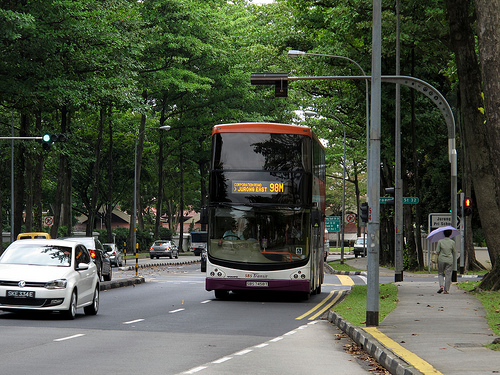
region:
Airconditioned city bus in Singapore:
[203, 123, 323, 298]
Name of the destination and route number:
[232, 180, 286, 198]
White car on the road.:
[0, 231, 97, 318]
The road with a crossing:
[0, 253, 360, 373]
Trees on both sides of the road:
[0, 80, 495, 270]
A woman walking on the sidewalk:
[435, 225, 455, 290]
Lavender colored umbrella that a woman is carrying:
[425, 225, 455, 236]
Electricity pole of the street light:
[365, 0, 377, 320]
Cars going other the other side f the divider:
[19, 233, 209, 277]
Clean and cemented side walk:
[347, 258, 498, 373]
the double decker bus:
[198, 104, 330, 309]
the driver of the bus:
[214, 215, 250, 250]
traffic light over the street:
[230, 61, 410, 131]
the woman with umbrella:
[411, 218, 461, 302]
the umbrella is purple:
[422, 216, 477, 242]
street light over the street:
[266, 31, 348, 80]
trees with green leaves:
[10, 10, 492, 115]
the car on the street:
[4, 233, 112, 311]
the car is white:
[5, 231, 107, 323]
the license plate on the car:
[3, 286, 37, 308]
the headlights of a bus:
[288, 270, 312, 282]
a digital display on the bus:
[226, 175, 291, 200]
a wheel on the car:
[61, 286, 81, 320]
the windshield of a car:
[0, 240, 76, 272]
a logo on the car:
[15, 275, 30, 291]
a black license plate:
[3, 285, 37, 303]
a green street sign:
[373, 193, 421, 207]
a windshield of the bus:
[204, 194, 312, 269]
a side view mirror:
[74, 259, 95, 273]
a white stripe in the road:
[158, 300, 189, 320]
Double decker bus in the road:
[182, 122, 314, 309]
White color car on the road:
[11, 248, 88, 331]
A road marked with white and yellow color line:
[162, 298, 318, 347]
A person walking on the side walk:
[423, 219, 468, 299]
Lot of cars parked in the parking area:
[93, 227, 178, 260]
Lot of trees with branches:
[58, 40, 200, 82]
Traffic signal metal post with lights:
[250, 69, 342, 100]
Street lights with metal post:
[280, 47, 360, 66]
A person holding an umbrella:
[423, 222, 458, 250]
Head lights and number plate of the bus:
[208, 266, 308, 290]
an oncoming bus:
[202, 122, 326, 301]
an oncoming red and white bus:
[203, 119, 326, 298]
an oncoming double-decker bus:
[204, 121, 327, 300]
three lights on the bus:
[290, 266, 307, 283]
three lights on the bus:
[209, 266, 224, 278]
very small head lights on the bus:
[208, 262, 313, 282]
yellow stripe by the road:
[365, 323, 437, 373]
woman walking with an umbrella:
[425, 223, 460, 295]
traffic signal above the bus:
[247, 71, 290, 95]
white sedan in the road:
[0, 238, 103, 319]